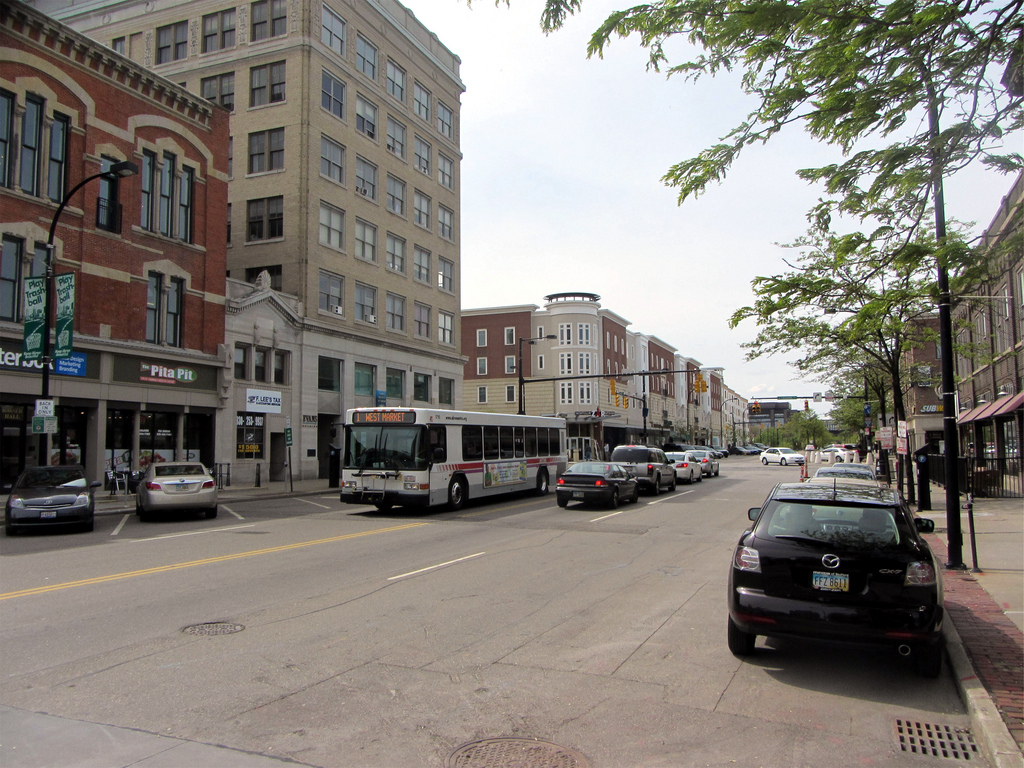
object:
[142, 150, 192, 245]
window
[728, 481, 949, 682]
car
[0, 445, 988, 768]
street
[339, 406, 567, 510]
bus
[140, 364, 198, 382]
sign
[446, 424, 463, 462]
white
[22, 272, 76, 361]
banners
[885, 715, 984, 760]
sewer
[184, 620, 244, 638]
holes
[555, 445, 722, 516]
cars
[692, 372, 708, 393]
light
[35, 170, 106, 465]
pole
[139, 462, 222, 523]
car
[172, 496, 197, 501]
silver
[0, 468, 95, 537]
car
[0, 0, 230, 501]
stories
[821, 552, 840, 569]
logo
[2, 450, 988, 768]
road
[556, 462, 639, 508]
stopped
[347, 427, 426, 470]
windshield